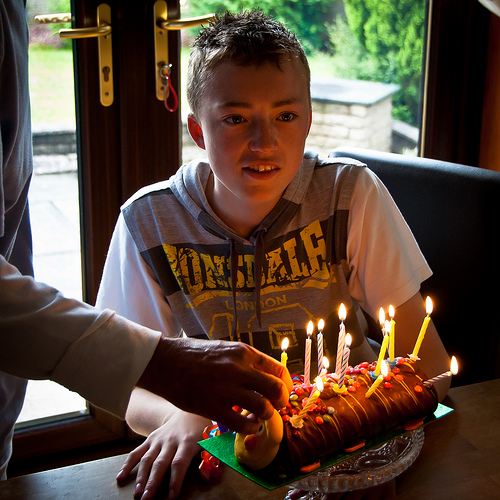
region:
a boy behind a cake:
[92, 23, 467, 460]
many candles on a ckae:
[266, 308, 453, 390]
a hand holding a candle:
[168, 321, 303, 443]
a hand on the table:
[101, 418, 256, 499]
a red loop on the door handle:
[160, 50, 186, 122]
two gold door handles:
[62, 8, 239, 95]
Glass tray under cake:
[192, 398, 444, 493]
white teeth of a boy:
[245, 162, 281, 177]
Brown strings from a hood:
[220, 233, 286, 349]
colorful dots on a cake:
[289, 374, 421, 404]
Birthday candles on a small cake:
[245, 291, 475, 438]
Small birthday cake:
[242, 288, 462, 468]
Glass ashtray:
[275, 416, 434, 497]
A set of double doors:
[0, 8, 477, 460]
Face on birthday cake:
[228, 400, 290, 480]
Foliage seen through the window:
[317, 3, 430, 92]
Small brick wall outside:
[310, 75, 407, 151]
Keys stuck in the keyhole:
[151, 54, 183, 122]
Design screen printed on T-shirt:
[151, 228, 336, 307]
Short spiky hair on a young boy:
[193, 8, 310, 81]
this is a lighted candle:
[423, 347, 469, 387]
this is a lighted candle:
[406, 290, 436, 358]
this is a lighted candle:
[375, 320, 393, 370]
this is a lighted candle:
[333, 318, 364, 389]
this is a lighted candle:
[291, 375, 332, 426]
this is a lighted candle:
[267, 323, 297, 404]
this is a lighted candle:
[295, 315, 311, 378]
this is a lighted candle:
[328, 306, 350, 371]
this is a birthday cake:
[197, 285, 462, 480]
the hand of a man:
[156, 316, 289, 436]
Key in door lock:
[156, 59, 181, 118]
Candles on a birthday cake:
[283, 293, 435, 389]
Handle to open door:
[59, 18, 117, 43]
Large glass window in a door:
[0, 5, 95, 448]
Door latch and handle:
[52, 4, 117, 107]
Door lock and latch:
[50, 6, 117, 111]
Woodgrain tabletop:
[469, 401, 494, 496]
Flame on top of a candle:
[302, 316, 317, 341]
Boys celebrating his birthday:
[80, 13, 462, 498]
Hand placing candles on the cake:
[138, 306, 306, 451]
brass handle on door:
[57, 23, 114, 40]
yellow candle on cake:
[410, 295, 436, 363]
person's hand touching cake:
[156, 326, 296, 431]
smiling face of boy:
[186, 13, 316, 204]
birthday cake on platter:
[198, 296, 460, 498]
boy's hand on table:
[114, 411, 219, 499]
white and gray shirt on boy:
[95, 149, 432, 416]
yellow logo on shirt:
[153, 219, 340, 310]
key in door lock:
[159, 63, 180, 113]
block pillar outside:
[304, 71, 397, 156]